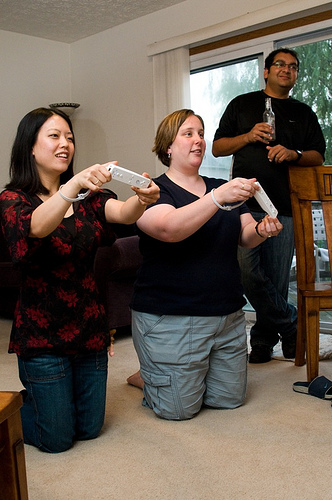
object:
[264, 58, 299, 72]
eyeglasses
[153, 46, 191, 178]
blinds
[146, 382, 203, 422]
knees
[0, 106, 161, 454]
asian girl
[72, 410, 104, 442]
knees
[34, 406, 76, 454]
knees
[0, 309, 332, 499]
floor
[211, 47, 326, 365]
man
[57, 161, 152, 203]
wii remote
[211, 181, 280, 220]
wii remote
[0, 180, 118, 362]
shirt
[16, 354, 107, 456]
jeans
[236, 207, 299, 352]
jeans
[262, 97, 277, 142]
bottle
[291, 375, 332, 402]
slipper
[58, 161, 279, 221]
wii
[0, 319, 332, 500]
carpet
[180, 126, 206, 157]
smiling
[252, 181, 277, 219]
white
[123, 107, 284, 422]
lady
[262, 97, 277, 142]
beer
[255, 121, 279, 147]
holding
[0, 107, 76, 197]
hair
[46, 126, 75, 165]
smiling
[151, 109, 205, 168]
hair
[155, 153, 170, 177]
white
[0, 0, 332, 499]
room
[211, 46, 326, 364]
standing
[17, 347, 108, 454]
kneeling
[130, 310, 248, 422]
pants